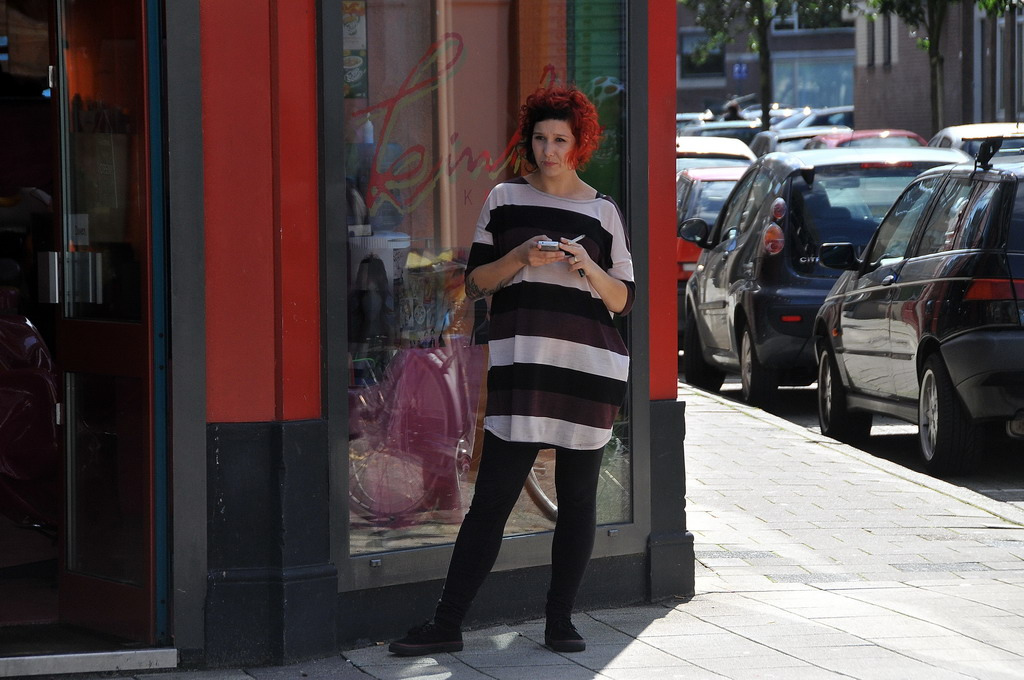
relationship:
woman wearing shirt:
[381, 83, 638, 659] [463, 178, 637, 460]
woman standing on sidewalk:
[381, 83, 638, 659] [282, 368, 1023, 673]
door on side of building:
[4, 0, 188, 677] [4, 0, 693, 675]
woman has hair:
[390, 83, 651, 662] [516, 87, 608, 176]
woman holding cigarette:
[390, 83, 651, 662] [562, 228, 592, 251]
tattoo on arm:
[457, 266, 503, 302] [457, 225, 528, 306]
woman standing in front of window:
[390, 83, 651, 662] [317, 4, 641, 537]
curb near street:
[758, 415, 985, 653] [677, 108, 1020, 514]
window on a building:
[331, 1, 656, 561] [4, 0, 693, 675]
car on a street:
[812, 160, 992, 470] [677, 3, 1022, 515]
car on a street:
[675, 137, 993, 412] [677, 3, 1022, 515]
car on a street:
[694, 150, 801, 317] [677, 3, 1022, 515]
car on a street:
[663, 85, 992, 457] [677, 3, 1022, 515]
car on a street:
[803, 134, 1019, 480] [677, 3, 1022, 515]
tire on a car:
[802, 338, 885, 449] [803, 134, 1019, 480]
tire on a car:
[897, 351, 984, 464] [803, 134, 1019, 480]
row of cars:
[661, 88, 1016, 488] [666, 133, 1022, 492]